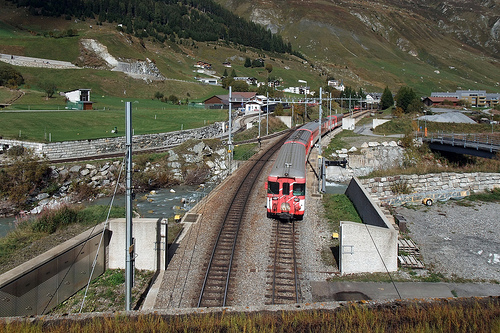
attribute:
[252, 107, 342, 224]
train — red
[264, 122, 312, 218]
train — old, red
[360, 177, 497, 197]
wall — rock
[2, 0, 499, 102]
mountain side — green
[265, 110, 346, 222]
train — Grey , White, Red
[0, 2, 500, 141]
hillside — green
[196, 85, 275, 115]
house — brown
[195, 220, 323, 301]
tracks — Rusted , Old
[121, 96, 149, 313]
pole — metal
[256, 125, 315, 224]
train — old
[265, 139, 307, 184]
roof — silver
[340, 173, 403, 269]
wall — gray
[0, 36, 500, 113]
hillside — grassy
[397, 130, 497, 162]
bridge — metal , Short 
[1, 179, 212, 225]
creek — Small 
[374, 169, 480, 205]
wall — stone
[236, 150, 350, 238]
train — red, old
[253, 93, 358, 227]
train — red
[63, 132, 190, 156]
wall — cobblestone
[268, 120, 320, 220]
train — red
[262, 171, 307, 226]
train — old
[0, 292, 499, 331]
grass — green , Brown 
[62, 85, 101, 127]
structure — white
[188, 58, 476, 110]
villiage — Small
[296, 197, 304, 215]
stripe — white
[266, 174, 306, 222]
train — old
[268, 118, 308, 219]
train — red